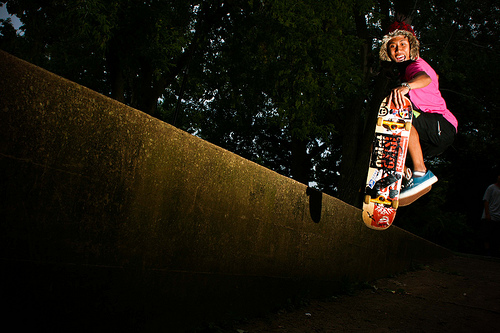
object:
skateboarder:
[377, 29, 459, 207]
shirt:
[406, 57, 458, 134]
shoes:
[397, 170, 438, 199]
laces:
[403, 168, 413, 183]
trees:
[0, 0, 499, 241]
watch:
[400, 82, 411, 91]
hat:
[380, 20, 420, 62]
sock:
[413, 171, 426, 178]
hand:
[387, 86, 410, 109]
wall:
[0, 48, 453, 333]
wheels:
[364, 118, 412, 209]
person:
[480, 176, 500, 257]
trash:
[305, 312, 312, 316]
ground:
[213, 252, 499, 333]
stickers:
[361, 95, 415, 231]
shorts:
[409, 113, 455, 159]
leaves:
[450, 317, 472, 333]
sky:
[1, 0, 499, 193]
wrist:
[399, 82, 413, 90]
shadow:
[306, 184, 323, 223]